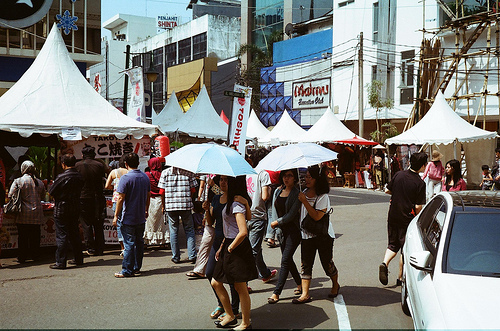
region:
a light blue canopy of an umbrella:
[164, 141, 259, 176]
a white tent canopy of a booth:
[0, 21, 157, 136]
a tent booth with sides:
[384, 88, 497, 188]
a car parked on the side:
[403, 189, 498, 329]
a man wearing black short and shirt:
[378, 151, 425, 284]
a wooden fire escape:
[436, 0, 498, 100]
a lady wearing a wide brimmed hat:
[430, 147, 441, 160]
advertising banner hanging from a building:
[231, 81, 253, 158]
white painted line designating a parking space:
[331, 291, 361, 330]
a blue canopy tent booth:
[176, 83, 227, 140]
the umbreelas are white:
[186, 140, 251, 172]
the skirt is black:
[206, 251, 254, 288]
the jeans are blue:
[113, 221, 156, 280]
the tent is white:
[23, 80, 118, 132]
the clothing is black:
[383, 178, 407, 247]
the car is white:
[404, 206, 499, 329]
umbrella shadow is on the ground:
[261, 297, 338, 328]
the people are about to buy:
[26, 152, 124, 257]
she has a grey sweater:
[267, 193, 297, 223]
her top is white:
[290, 194, 342, 239]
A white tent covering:
[0, 18, 162, 140]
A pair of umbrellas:
[156, 140, 351, 189]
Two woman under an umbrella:
[255, 147, 347, 301]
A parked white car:
[403, 188, 498, 329]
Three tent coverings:
[243, 110, 366, 152]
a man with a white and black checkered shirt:
[157, 162, 203, 222]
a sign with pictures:
[93, 136, 154, 159]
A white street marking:
[324, 283, 361, 328]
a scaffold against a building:
[430, 9, 498, 119]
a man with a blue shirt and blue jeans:
[103, 149, 155, 278]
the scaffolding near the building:
[401, 22, 498, 182]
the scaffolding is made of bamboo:
[413, 7, 493, 175]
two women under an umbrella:
[156, 142, 276, 325]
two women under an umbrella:
[243, 133, 350, 317]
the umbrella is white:
[149, 144, 257, 199]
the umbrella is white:
[256, 143, 340, 184]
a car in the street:
[398, 187, 497, 328]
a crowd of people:
[17, 152, 213, 278]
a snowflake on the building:
[52, 3, 84, 50]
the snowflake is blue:
[43, 5, 88, 40]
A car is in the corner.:
[395, 182, 498, 329]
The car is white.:
[387, 177, 497, 329]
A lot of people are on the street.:
[9, 125, 364, 315]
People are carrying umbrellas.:
[142, 124, 356, 321]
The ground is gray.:
[41, 283, 161, 320]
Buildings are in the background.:
[108, 6, 497, 188]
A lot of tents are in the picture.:
[7, 27, 492, 164]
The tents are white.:
[228, 92, 496, 155]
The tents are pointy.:
[232, 77, 497, 163]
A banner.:
[213, 75, 259, 182]